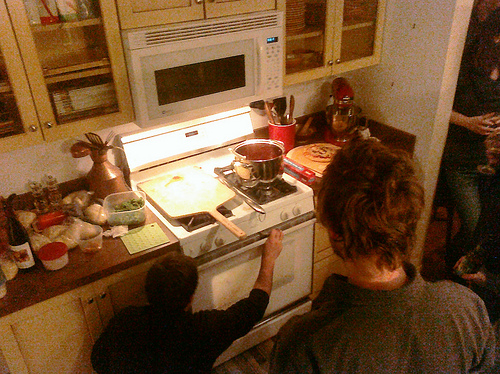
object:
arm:
[448, 110, 472, 134]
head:
[144, 254, 199, 313]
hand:
[467, 112, 494, 135]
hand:
[262, 228, 284, 258]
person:
[89, 227, 284, 374]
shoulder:
[268, 301, 344, 370]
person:
[271, 140, 496, 374]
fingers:
[475, 112, 495, 136]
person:
[442, 9, 500, 275]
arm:
[205, 259, 274, 349]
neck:
[347, 247, 408, 290]